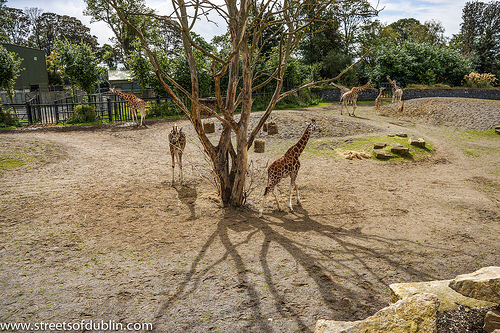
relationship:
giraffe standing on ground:
[167, 122, 188, 187] [1, 97, 500, 331]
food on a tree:
[202, 123, 215, 132] [83, 1, 378, 206]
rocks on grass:
[374, 129, 426, 158] [281, 124, 447, 162]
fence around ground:
[5, 82, 499, 127] [1, 97, 500, 331]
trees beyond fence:
[1, 1, 500, 81] [5, 82, 499, 127]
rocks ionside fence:
[374, 129, 426, 158] [5, 82, 499, 127]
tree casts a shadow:
[83, 1, 378, 206] [152, 212, 433, 333]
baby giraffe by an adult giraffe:
[372, 84, 389, 116] [340, 81, 375, 118]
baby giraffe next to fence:
[372, 84, 389, 116] [5, 82, 499, 127]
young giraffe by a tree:
[259, 116, 324, 217] [83, 1, 378, 206]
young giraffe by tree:
[167, 122, 188, 187] [83, 1, 378, 206]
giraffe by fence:
[109, 81, 147, 126] [5, 82, 499, 127]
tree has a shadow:
[83, 1, 378, 206] [152, 212, 433, 333]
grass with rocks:
[281, 124, 447, 162] [374, 129, 426, 158]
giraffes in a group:
[334, 73, 410, 115] [341, 68, 409, 118]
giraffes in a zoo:
[334, 73, 410, 115] [3, 3, 499, 332]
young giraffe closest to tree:
[259, 116, 324, 217] [83, 1, 378, 206]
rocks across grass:
[374, 129, 426, 158] [281, 124, 447, 162]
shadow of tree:
[152, 212, 433, 333] [83, 1, 378, 206]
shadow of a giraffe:
[173, 179, 201, 225] [167, 122, 188, 187]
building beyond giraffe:
[96, 68, 222, 104] [109, 81, 147, 126]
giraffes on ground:
[334, 73, 410, 115] [1, 97, 500, 331]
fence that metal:
[5, 82, 499, 127] [9, 101, 161, 122]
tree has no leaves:
[83, 1, 378, 206] [61, 41, 100, 84]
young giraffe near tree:
[259, 116, 324, 217] [83, 1, 378, 206]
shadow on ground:
[152, 212, 433, 333] [1, 97, 500, 331]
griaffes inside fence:
[341, 68, 409, 118] [5, 82, 499, 127]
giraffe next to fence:
[109, 81, 147, 126] [5, 82, 499, 127]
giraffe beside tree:
[167, 122, 188, 187] [83, 1, 378, 206]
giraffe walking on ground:
[167, 122, 188, 187] [1, 97, 500, 331]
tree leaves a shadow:
[83, 1, 378, 206] [152, 212, 433, 333]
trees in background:
[1, 1, 500, 81] [5, 2, 500, 141]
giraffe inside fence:
[167, 122, 188, 187] [5, 82, 499, 127]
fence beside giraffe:
[5, 82, 499, 127] [109, 81, 147, 126]